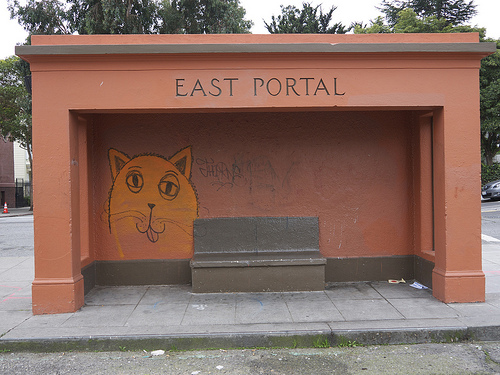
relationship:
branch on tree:
[0, 41, 45, 158] [2, 57, 36, 177]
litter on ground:
[334, 283, 478, 320] [270, 275, 438, 317]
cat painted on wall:
[96, 146, 200, 260] [80, 117, 432, 282]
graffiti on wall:
[197, 147, 301, 196] [88, 112, 417, 254]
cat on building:
[96, 146, 200, 260] [17, 31, 493, 313]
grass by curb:
[266, 321, 384, 371] [229, 313, 456, 344]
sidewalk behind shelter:
[6, 220, 40, 315] [15, 29, 488, 314]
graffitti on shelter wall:
[93, 150, 200, 258] [179, 132, 430, 257]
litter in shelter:
[386, 278, 427, 291] [15, 29, 488, 314]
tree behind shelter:
[13, 0, 248, 32] [15, 29, 488, 314]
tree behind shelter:
[257, 0, 345, 30] [15, 29, 488, 314]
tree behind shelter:
[380, 1, 482, 31] [15, 29, 488, 314]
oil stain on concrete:
[226, 335, 355, 373] [0, 337, 499, 373]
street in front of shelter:
[0, 337, 498, 371] [15, 29, 488, 314]